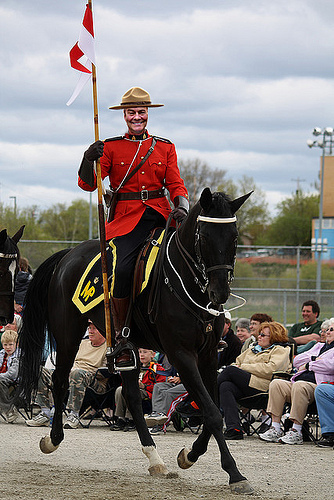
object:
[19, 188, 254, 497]
horse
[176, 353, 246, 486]
leg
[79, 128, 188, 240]
jacket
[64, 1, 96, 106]
flag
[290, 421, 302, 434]
slacks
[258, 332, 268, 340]
sunglasses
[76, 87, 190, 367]
man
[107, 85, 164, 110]
hat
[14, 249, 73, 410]
tail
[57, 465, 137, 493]
rocks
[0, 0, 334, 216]
sky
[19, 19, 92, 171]
cloud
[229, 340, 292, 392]
jacket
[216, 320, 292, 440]
woman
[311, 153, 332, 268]
building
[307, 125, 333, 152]
light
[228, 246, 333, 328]
fence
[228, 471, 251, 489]
hoof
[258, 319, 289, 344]
hair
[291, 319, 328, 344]
shirt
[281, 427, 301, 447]
sneakers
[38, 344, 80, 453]
pants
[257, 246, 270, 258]
car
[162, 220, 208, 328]
bridle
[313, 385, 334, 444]
people